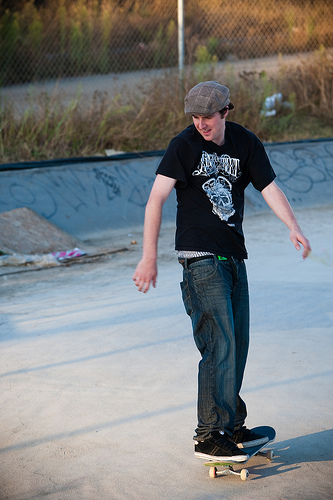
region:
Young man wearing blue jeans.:
[162, 226, 296, 485]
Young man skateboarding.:
[31, 2, 306, 490]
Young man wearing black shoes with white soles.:
[183, 379, 282, 487]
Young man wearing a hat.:
[123, 72, 287, 158]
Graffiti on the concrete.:
[0, 161, 148, 216]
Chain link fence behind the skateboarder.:
[7, 0, 330, 178]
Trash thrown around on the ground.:
[12, 116, 129, 311]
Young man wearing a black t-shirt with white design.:
[122, 72, 323, 298]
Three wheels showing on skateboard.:
[184, 413, 300, 488]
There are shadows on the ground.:
[8, 255, 331, 493]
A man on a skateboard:
[127, 78, 316, 482]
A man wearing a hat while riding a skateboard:
[127, 79, 317, 482]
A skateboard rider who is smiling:
[124, 79, 316, 482]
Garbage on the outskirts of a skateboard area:
[0, 203, 142, 278]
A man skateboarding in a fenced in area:
[3, 1, 332, 480]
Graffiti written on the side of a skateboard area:
[0, 135, 332, 212]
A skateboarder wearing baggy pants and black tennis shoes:
[132, 80, 314, 482]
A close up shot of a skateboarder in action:
[0, 4, 329, 499]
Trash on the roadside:
[1, 53, 332, 167]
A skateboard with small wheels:
[189, 417, 290, 486]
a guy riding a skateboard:
[127, 70, 327, 484]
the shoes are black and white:
[187, 411, 281, 492]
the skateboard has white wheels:
[196, 441, 284, 493]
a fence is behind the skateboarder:
[1, 0, 327, 176]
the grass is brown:
[3, 57, 328, 153]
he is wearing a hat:
[165, 74, 247, 149]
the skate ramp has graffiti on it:
[10, 138, 330, 240]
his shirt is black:
[151, 114, 278, 272]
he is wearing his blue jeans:
[167, 242, 266, 460]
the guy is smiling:
[178, 81, 246, 157]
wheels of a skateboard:
[239, 472, 245, 479]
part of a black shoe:
[211, 450, 225, 452]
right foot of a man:
[206, 433, 221, 450]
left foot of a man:
[233, 431, 251, 436]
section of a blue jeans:
[202, 342, 217, 407]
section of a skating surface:
[111, 398, 146, 431]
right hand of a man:
[148, 192, 162, 254]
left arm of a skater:
[275, 195, 294, 228]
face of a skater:
[192, 124, 220, 133]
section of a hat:
[205, 90, 215, 100]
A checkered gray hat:
[175, 75, 235, 119]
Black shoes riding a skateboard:
[192, 422, 284, 481]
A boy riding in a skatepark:
[127, 82, 274, 480]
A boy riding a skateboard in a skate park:
[135, 61, 316, 486]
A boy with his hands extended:
[129, 75, 308, 290]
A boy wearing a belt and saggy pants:
[180, 246, 259, 430]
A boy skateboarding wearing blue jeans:
[130, 72, 287, 481]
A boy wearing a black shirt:
[137, 132, 313, 299]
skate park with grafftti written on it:
[3, 163, 149, 219]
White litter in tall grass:
[253, 72, 313, 121]